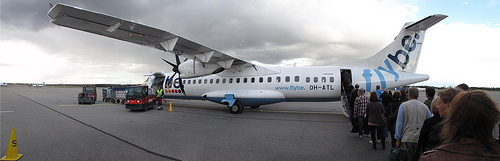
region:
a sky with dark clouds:
[0, 2, 499, 75]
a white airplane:
[35, 1, 452, 105]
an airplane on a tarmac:
[6, 2, 493, 146]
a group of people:
[327, 54, 495, 159]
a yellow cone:
[0, 118, 44, 158]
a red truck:
[109, 74, 194, 121]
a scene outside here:
[3, 1, 478, 154]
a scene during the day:
[5, 2, 497, 142]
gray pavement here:
[12, 80, 267, 160]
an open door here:
[331, 66, 359, 114]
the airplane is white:
[42, 4, 446, 114]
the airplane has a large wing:
[45, 7, 243, 73]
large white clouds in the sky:
[0, 5, 357, 91]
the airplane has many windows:
[186, 77, 334, 86]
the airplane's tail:
[348, 1, 439, 80]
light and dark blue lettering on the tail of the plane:
[352, 10, 442, 80]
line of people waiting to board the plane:
[345, 76, 482, 159]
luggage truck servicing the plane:
[124, 79, 167, 114]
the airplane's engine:
[194, 83, 286, 111]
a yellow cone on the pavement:
[3, 129, 33, 158]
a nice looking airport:
[39, 10, 449, 157]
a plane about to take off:
[97, 20, 450, 128]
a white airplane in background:
[154, 53, 391, 145]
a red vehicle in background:
[116, 84, 201, 136]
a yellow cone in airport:
[5, 118, 28, 159]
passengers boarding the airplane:
[339, 74, 452, 157]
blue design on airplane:
[325, 46, 495, 121]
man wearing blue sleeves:
[395, 86, 456, 158]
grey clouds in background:
[27, 8, 419, 157]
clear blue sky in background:
[324, 0, 498, 90]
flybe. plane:
[39, 16, 446, 88]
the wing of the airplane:
[30, 5, 250, 67]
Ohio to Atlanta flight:
[265, 76, 348, 98]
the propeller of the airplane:
[154, 51, 194, 99]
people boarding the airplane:
[389, 98, 498, 146]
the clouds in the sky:
[238, 0, 360, 55]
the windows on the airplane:
[178, 72, 345, 92]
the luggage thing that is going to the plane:
[76, 77, 188, 119]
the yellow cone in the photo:
[5, 132, 30, 154]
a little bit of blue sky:
[456, 0, 488, 24]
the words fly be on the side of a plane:
[358, 44, 431, 89]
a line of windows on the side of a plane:
[204, 72, 341, 82]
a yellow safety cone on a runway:
[3, 126, 28, 158]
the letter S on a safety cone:
[12, 137, 18, 146]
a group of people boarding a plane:
[345, 83, 485, 158]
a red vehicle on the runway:
[127, 82, 155, 117]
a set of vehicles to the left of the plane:
[78, 81, 133, 106]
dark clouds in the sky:
[203, 2, 368, 42]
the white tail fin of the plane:
[386, 5, 445, 70]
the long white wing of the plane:
[41, 4, 240, 67]